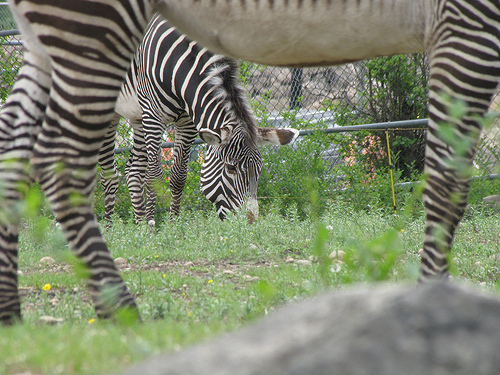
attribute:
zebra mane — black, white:
[208, 67, 257, 148]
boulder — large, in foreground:
[202, 316, 480, 371]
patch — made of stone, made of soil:
[146, 241, 362, 290]